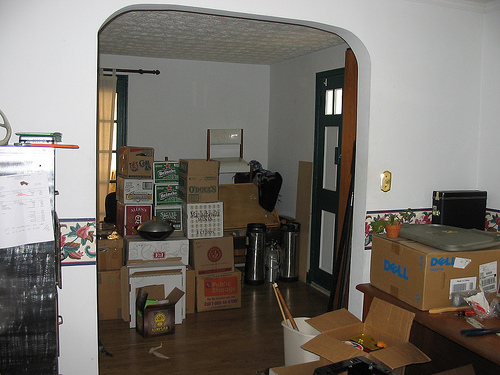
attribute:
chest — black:
[428, 186, 491, 229]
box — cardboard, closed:
[152, 182, 183, 204]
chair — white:
[203, 125, 253, 185]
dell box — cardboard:
[368, 225, 498, 313]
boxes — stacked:
[96, 147, 241, 337]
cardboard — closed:
[112, 141, 172, 187]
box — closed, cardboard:
[152, 160, 180, 184]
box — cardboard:
[179, 156, 219, 203]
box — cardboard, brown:
[176, 157, 223, 203]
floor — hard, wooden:
[100, 229, 442, 373]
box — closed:
[190, 236, 235, 276]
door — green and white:
[311, 67, 344, 297]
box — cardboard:
[117, 147, 153, 178]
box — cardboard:
[182, 202, 224, 239]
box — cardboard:
[193, 235, 234, 276]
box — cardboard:
[198, 270, 241, 312]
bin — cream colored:
[279, 315, 324, 363]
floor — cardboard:
[99, 332, 266, 371]